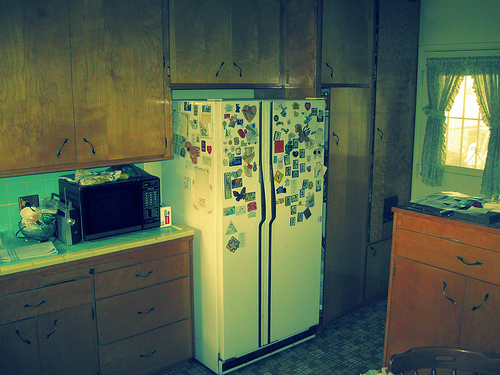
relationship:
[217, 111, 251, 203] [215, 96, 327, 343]
stickers on fridge door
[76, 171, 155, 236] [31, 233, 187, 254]
microwave oven on countertop